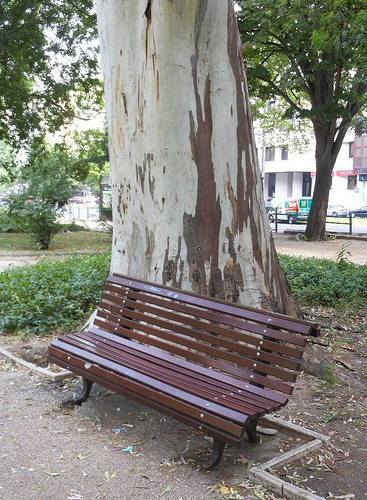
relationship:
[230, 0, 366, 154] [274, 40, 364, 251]
leaves on tree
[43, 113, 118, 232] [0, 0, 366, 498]
building near park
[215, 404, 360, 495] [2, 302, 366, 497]
leaves on ground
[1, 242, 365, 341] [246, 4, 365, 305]
greenery around tree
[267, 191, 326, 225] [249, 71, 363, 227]
van parked in front of a building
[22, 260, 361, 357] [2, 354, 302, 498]
leaves on ground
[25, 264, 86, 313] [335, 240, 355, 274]
leaves of plants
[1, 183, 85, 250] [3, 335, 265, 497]
bush on walkway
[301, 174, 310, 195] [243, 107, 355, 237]
window of building